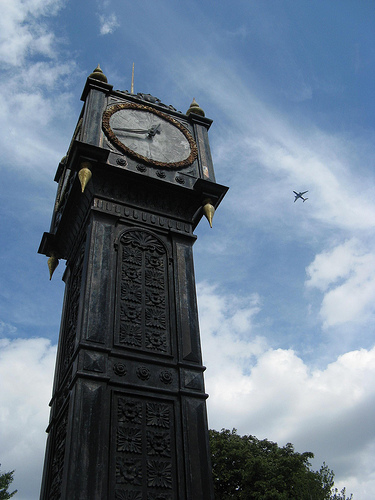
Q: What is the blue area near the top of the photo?
A: The sky.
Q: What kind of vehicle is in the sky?
A: A plane.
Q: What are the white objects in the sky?
A: Clouds.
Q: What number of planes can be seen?
A: One.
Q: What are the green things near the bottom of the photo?
A: Trees.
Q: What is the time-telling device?
A: A clock.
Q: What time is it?
A: 12:42PM.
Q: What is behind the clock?
A: A Tree.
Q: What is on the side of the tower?
A: Ornate designs.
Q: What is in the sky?
A: Planes.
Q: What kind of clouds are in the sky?
A: Cumulus.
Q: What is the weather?
A: Mostly sunny.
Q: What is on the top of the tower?
A: A clock.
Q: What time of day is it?
A: Afternoon.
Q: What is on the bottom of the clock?
A: Spikes.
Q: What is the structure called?
A: A clock tower.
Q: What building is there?
A: Clock tower.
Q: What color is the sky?
A: Blue.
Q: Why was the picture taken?
A: To show a monumental clock.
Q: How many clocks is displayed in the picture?
A: One.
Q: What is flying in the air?
A: A plane.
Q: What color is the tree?
A: Green.